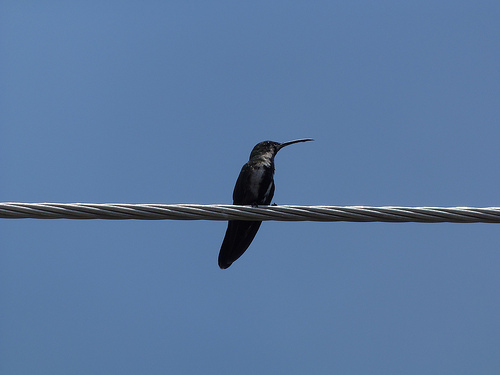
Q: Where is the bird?
A: Sitting on a wire.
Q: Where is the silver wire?
A: Under the bird.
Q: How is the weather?
A: Clear and sunny.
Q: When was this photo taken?
A: During the daytime.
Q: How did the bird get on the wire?
A: It flew there.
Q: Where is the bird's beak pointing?
A: Toward the right.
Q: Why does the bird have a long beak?
A: For drinking nectar.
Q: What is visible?
A: A bird.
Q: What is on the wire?
A: A bird.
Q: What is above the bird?
A: The sky.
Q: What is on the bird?
A: A beak.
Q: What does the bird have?
A: Feathers.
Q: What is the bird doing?
A: Sitting on wire.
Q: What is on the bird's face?
A: The beak.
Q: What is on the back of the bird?
A: Tail feather.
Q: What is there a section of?
A: Rope.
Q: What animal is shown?
A: Bird.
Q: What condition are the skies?
A: Clear.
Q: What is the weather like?
A: Sunny.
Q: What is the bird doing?
A: Sitting still.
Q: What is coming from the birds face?
A: Beak.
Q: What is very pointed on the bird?
A: Beak.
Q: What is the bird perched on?
A: Electrical wire.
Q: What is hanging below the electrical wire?
A: Tail.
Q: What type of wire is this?
A: Electrical wire.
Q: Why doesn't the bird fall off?
A: He is holding on with his feet.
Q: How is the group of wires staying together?
A: They are coiled together.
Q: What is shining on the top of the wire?
A: Sunshine.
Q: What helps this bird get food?
A: Very long beak.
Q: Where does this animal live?
A: In nests.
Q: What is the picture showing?
A: A bird.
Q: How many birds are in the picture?
A: One.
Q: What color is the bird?
A: Black.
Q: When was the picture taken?
A: During the day.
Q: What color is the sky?
A: Blue.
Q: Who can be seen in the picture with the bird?
A: No one.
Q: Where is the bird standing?
A: On a wire.